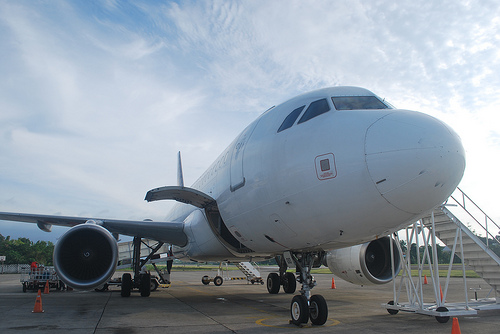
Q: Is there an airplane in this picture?
A: Yes, there is an airplane.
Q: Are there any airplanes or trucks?
A: Yes, there is an airplane.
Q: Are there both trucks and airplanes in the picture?
A: No, there is an airplane but no trucks.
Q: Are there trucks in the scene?
A: No, there are no trucks.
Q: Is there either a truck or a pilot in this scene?
A: No, there are no trucks or pilots.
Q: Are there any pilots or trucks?
A: No, there are no trucks or pilots.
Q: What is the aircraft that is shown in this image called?
A: The aircraft is an airplane.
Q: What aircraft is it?
A: The aircraft is an airplane.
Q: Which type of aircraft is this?
A: This is an airplane.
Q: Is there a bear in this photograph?
A: No, there are no bears.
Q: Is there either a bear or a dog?
A: No, there are no bears or dogs.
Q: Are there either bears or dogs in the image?
A: No, there are no bears or dogs.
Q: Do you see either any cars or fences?
A: No, there are no fences or cars.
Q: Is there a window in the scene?
A: Yes, there is a window.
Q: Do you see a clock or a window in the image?
A: Yes, there is a window.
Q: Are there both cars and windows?
A: No, there is a window but no cars.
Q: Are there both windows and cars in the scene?
A: No, there is a window but no cars.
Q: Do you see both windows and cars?
A: No, there is a window but no cars.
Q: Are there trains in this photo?
A: No, there are no trains.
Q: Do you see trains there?
A: No, there are no trains.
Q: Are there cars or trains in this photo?
A: No, there are no trains or cars.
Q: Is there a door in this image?
A: Yes, there is a door.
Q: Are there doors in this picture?
A: Yes, there is a door.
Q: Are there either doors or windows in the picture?
A: Yes, there is a door.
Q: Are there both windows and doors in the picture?
A: Yes, there are both a door and a window.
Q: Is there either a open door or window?
A: Yes, there is an open door.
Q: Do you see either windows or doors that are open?
A: Yes, the door is open.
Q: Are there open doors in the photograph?
A: Yes, there is an open door.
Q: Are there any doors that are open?
A: Yes, there is a door that is open.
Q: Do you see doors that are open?
A: Yes, there is a door that is open.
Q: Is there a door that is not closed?
A: Yes, there is a open door.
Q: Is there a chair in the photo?
A: No, there are no chairs.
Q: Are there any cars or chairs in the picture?
A: No, there are no chairs or cars.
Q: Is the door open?
A: Yes, the door is open.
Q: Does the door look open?
A: Yes, the door is open.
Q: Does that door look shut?
A: No, the door is open.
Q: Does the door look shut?
A: No, the door is open.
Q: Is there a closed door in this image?
A: No, there is a door but it is open.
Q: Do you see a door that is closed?
A: No, there is a door but it is open.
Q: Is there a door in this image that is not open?
A: No, there is a door but it is open.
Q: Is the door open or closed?
A: The door is open.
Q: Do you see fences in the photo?
A: No, there are no fences.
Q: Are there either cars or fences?
A: No, there are no fences or cars.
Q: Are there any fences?
A: No, there are no fences.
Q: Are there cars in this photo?
A: No, there are no cars.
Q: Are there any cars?
A: No, there are no cars.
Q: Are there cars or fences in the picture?
A: No, there are no cars or fences.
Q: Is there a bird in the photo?
A: No, there are no birds.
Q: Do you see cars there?
A: No, there are no cars.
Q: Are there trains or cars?
A: No, there are no cars or trains.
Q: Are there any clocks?
A: No, there are no clocks.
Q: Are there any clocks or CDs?
A: No, there are no clocks or cds.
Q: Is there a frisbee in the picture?
A: No, there are no frisbees.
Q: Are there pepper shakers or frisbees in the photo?
A: No, there are no frisbees or pepper shakers.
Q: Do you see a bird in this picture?
A: No, there are no birds.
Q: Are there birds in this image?
A: No, there are no birds.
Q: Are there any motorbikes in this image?
A: No, there are no motorbikes.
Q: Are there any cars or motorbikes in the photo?
A: No, there are no motorbikes or cars.